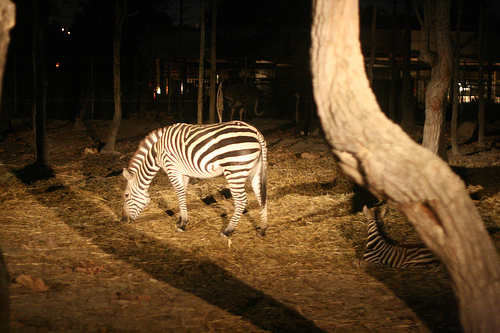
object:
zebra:
[362, 204, 443, 270]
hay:
[18, 217, 364, 280]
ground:
[0, 118, 499, 333]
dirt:
[226, 237, 341, 295]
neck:
[127, 142, 163, 190]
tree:
[310, 0, 500, 332]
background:
[0, 0, 499, 332]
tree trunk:
[310, 0, 499, 332]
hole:
[419, 198, 447, 234]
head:
[121, 167, 150, 222]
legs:
[248, 170, 270, 239]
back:
[218, 169, 249, 238]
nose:
[122, 206, 144, 231]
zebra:
[121, 120, 269, 238]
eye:
[124, 193, 129, 197]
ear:
[122, 167, 132, 180]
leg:
[164, 167, 190, 233]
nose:
[120, 213, 127, 222]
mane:
[132, 151, 159, 181]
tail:
[255, 138, 268, 209]